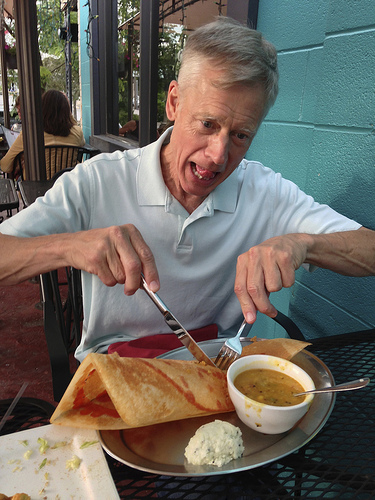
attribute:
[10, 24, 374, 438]
man — older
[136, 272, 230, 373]
knife — silver, gray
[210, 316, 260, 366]
fork — gray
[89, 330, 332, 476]
platter — silver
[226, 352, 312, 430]
cup — small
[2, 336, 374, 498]
table — black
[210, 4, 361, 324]
wall — greenish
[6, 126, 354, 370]
shirt — white, blue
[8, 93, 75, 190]
woman — sitting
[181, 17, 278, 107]
hair — gray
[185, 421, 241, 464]
potatoes — white, creamy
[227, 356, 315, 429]
bowl — white, small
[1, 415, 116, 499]
plate — white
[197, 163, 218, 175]
tounge — out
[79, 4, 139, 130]
lights — hanging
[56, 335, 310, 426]
tortilla — large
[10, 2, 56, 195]
pillar — brown